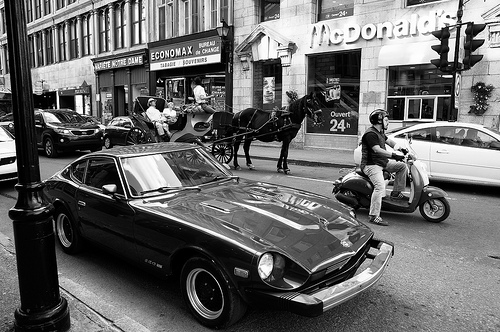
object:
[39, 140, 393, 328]
car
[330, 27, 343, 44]
letter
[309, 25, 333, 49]
letter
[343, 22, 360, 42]
letter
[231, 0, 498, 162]
building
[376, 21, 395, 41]
letter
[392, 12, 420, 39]
letter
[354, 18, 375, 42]
letter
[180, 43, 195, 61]
letter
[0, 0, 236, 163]
building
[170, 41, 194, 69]
letter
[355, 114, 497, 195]
car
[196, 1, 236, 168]
street lamp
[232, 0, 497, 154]
mcdonalds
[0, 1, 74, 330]
streetlamp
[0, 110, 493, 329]
street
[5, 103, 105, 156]
truck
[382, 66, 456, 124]
windows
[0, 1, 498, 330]
picture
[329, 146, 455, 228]
scooter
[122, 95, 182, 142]
couple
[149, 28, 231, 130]
stores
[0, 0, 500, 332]
city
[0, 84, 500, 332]
vehicles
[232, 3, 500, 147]
buildings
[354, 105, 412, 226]
man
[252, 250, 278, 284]
headlight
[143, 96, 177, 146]
man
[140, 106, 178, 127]
shirt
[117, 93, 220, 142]
buggy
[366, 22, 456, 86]
sign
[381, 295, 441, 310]
stains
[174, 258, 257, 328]
rims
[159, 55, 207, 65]
letter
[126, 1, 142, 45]
window pane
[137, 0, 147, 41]
window pane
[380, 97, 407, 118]
window pane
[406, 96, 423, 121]
window pane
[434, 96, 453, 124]
window pane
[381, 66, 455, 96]
window pane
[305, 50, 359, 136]
window pane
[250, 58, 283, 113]
window pane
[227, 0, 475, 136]
city building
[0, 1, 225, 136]
city building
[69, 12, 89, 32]
window pane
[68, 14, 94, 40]
window pane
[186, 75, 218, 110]
person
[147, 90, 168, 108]
hat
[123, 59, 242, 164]
carrage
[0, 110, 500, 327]
road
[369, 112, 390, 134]
helmet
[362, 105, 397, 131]
head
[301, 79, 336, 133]
head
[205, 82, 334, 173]
horse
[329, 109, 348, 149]
number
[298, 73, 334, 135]
horse face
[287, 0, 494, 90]
lettering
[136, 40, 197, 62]
word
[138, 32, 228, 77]
sign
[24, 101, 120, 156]
suv